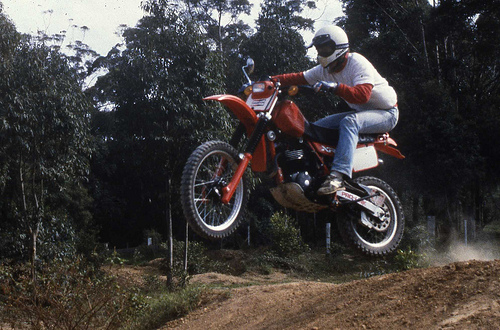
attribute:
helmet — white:
[311, 24, 353, 70]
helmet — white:
[303, 19, 351, 72]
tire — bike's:
[205, 159, 233, 218]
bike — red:
[176, 92, 408, 247]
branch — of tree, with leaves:
[12, 36, 132, 261]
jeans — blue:
[311, 103, 401, 178]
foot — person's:
[314, 167, 349, 199]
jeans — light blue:
[295, 104, 461, 216]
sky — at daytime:
[5, 8, 342, 44]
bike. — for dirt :
[138, 65, 453, 285]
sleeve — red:
[269, 72, 308, 88]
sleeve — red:
[336, 79, 371, 100]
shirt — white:
[302, 54, 395, 104]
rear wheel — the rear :
[337, 174, 407, 261]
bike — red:
[186, 24, 420, 260]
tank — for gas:
[274, 103, 311, 139]